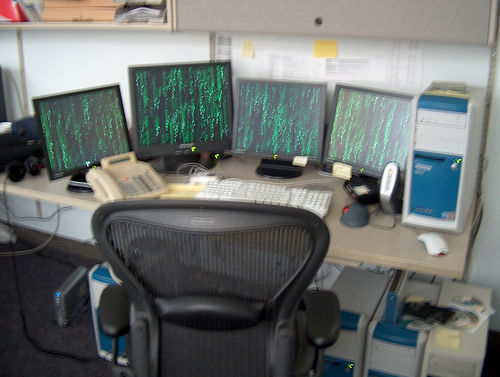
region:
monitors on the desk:
[42, 67, 402, 196]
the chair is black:
[81, 196, 303, 373]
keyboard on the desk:
[180, 166, 345, 227]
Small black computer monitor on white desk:
[10, 78, 132, 175]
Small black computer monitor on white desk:
[132, 57, 220, 166]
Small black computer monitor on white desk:
[235, 62, 323, 192]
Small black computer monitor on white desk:
[325, 81, 404, 213]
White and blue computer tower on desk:
[388, 74, 468, 271]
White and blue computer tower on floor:
[430, 279, 495, 370]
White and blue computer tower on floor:
[366, 269, 403, 374]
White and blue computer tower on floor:
[313, 276, 364, 372]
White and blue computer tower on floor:
[79, 256, 136, 374]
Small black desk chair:
[59, 172, 358, 370]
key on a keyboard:
[317, 186, 336, 203]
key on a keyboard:
[310, 190, 317, 197]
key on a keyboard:
[292, 185, 301, 195]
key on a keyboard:
[271, 188, 281, 193]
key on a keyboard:
[256, 186, 263, 190]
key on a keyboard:
[237, 178, 249, 186]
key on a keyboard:
[225, 185, 234, 193]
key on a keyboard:
[211, 180, 223, 194]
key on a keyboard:
[217, 195, 225, 199]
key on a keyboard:
[245, 197, 260, 206]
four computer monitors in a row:
[38, 59, 411, 176]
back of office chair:
[96, 199, 339, 374]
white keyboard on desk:
[183, 176, 335, 213]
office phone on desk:
[87, 151, 163, 206]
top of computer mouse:
[419, 231, 449, 256]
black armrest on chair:
[302, 287, 342, 344]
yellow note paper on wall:
[312, 38, 336, 58]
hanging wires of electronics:
[3, 185, 67, 356]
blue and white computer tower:
[402, 82, 484, 232]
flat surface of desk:
[1, 155, 475, 277]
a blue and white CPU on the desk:
[403, 82, 485, 232]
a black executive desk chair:
[90, 195, 340, 375]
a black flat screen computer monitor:
[32, 83, 132, 180]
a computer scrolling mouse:
[338, 199, 373, 227]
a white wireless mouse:
[416, 231, 450, 257]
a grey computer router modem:
[52, 264, 89, 331]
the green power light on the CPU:
[454, 157, 464, 164]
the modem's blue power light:
[54, 287, 61, 298]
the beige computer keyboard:
[198, 177, 333, 217]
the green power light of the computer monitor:
[190, 146, 197, 153]